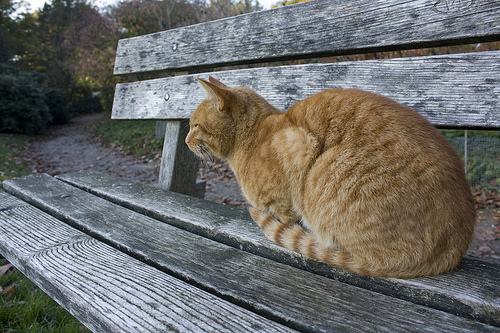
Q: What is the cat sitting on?
A: A bench.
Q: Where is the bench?
A: Next to a pathway.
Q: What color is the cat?
A: Ginger.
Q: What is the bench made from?
A: Wood.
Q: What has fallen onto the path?
A: Leaves.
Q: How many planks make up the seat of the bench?
A: Threee.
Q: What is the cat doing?
A: Sitting on the bench.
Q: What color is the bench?
A: Grey.